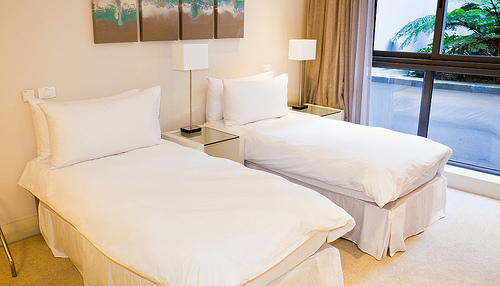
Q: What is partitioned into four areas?
A: Window.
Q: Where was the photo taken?
A: Hotel.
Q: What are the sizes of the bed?
A: Twin.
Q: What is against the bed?
A: Pillow.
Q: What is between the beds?
A: Table.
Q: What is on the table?
A: Lamps.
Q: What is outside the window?
A: Trees.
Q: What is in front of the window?
A: Curtain.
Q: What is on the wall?
A: Painting.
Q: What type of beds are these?
A: Twin beds.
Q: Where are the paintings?
A: On the wall.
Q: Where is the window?
A: On the right.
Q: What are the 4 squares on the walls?
A: Paintings.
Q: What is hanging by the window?
A: Curtains.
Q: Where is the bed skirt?
A: Around the bed.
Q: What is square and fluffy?
A: Pillows.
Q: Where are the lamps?
A: On the night stand.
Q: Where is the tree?
A: Outside window.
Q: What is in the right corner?
A: Lamp.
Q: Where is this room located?
A: Hotel.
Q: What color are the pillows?
A: White.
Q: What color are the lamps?
A: White and gold.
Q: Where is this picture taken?
A: Hotel.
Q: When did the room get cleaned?
A: Yesterday.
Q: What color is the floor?
A: Gold.